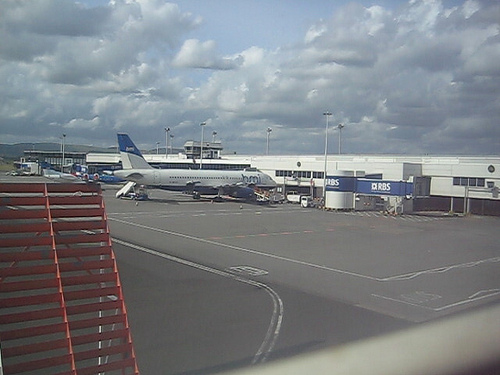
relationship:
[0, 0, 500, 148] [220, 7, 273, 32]
dark clouds in sky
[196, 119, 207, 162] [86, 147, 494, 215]
lightposts around building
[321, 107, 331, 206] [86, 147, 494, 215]
lightposts around building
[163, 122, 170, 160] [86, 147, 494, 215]
lightposts around building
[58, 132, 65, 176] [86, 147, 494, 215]
lightposts around building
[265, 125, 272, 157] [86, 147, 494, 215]
lightposts around building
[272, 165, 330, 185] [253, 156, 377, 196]
windows on building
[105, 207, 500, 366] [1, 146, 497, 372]
lines on tarmac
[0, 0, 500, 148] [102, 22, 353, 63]
dark clouds in sky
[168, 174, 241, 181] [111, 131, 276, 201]
windows on plane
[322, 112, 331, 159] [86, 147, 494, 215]
lights on building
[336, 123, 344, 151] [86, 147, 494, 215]
lights on building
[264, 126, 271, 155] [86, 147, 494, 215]
lights on building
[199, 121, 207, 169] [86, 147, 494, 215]
lightposts on building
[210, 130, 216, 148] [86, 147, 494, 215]
lights on building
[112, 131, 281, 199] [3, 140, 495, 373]
airplane parked at airport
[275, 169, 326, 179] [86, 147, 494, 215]
windows on building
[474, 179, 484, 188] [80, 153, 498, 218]
window on building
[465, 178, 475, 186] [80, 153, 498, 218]
window on building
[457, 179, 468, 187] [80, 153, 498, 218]
window on building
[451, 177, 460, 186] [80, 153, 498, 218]
window on building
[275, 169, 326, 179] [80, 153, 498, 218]
windows on building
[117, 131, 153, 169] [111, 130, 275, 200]
tail on airplane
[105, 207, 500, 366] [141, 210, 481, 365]
lines on tarmac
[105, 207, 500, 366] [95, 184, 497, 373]
lines on tarmac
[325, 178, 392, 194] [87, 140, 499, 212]
logo on building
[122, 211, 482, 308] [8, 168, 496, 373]
lines on cement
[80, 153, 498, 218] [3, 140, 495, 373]
building at airport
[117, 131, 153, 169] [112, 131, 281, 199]
tail of airplane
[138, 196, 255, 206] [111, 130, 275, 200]
shadow of airplane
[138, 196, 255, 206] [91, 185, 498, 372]
shadow on ground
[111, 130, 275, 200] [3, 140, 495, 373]
airplane parked in airport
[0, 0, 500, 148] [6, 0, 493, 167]
dark clouds in sky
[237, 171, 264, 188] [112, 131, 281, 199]
blue logo on airplane